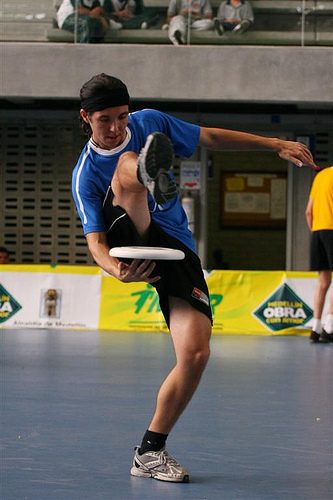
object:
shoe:
[136, 130, 178, 202]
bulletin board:
[219, 170, 288, 229]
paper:
[254, 191, 269, 214]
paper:
[239, 189, 255, 209]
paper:
[224, 191, 241, 212]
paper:
[223, 173, 246, 191]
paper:
[246, 176, 265, 186]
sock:
[306, 312, 323, 336]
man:
[305, 154, 333, 342]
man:
[71, 72, 318, 443]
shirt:
[71, 109, 198, 258]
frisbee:
[105, 244, 188, 261]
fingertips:
[130, 259, 141, 271]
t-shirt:
[309, 165, 333, 228]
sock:
[132, 424, 169, 453]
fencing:
[1, 264, 332, 333]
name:
[263, 300, 305, 325]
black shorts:
[103, 194, 216, 330]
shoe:
[129, 443, 191, 483]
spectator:
[167, 3, 215, 41]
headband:
[80, 84, 129, 113]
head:
[78, 71, 129, 148]